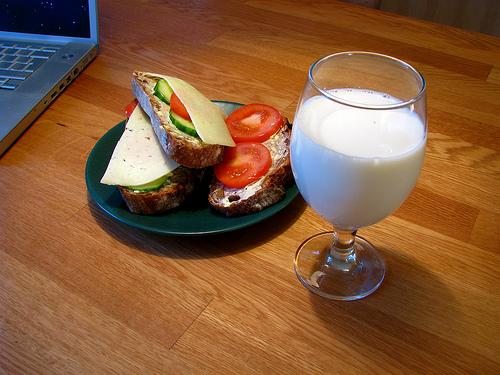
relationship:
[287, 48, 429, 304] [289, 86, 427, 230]
glass full of milk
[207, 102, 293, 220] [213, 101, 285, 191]
toast with tomato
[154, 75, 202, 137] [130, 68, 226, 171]
cucumber on toast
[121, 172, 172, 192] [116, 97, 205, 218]
cucumber on toast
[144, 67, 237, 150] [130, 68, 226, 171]
cheese on toast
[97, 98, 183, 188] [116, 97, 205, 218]
cheese on toast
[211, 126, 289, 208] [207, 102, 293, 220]
butter on toast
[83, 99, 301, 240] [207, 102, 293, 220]
saucer holds toast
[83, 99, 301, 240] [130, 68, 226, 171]
saucer holds toast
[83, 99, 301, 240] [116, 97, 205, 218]
saucer holds toast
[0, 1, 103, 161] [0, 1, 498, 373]
laptop on table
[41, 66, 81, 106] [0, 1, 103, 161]
ports on laptop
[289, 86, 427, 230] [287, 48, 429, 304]
milk in glass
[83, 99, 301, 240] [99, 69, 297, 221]
saucer contains food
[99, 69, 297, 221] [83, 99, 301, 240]
food on saucer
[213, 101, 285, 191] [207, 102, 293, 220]
tomato on toast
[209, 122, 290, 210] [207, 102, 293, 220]
butter on toast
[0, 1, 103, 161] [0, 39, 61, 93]
laptop has keys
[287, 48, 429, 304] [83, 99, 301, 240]
glass to right of saucer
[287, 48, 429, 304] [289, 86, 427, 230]
glass has milk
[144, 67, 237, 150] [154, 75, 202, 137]
cheese on cucumber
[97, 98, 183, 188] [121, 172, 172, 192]
cheese on cucumber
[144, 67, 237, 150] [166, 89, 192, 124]
cheese on tomato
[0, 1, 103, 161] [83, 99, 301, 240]
laptop to left of saucer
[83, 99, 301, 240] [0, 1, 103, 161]
saucer near laptop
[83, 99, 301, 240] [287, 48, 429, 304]
saucer near glass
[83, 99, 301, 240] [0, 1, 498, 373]
saucer on table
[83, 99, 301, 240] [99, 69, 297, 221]
saucer holds food